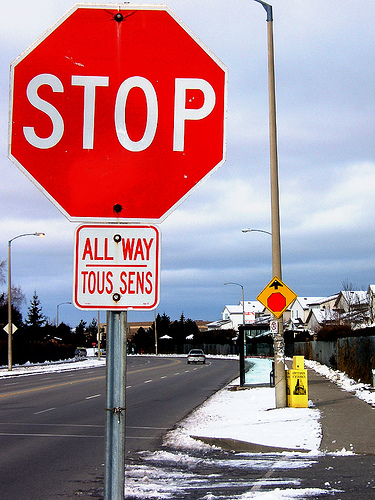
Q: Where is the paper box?
A: Against the pole.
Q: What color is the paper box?
A: Yellow.